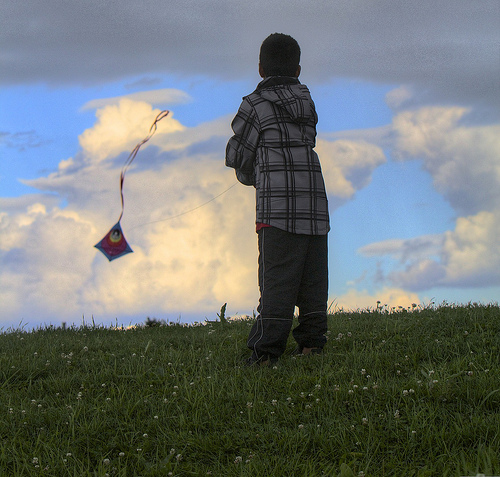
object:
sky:
[0, 1, 497, 333]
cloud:
[0, 73, 500, 318]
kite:
[92, 110, 169, 262]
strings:
[117, 108, 172, 224]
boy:
[225, 32, 330, 369]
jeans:
[246, 222, 328, 355]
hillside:
[0, 304, 500, 476]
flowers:
[0, 325, 497, 476]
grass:
[2, 302, 499, 475]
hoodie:
[225, 75, 330, 234]